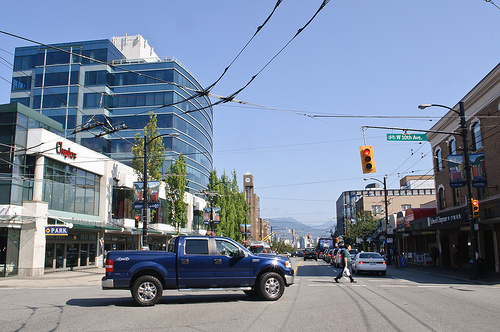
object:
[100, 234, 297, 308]
truck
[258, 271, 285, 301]
wheel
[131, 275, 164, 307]
wheel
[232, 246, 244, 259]
mirror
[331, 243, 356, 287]
man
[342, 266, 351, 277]
grocery bag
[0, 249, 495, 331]
street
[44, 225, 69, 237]
parking sign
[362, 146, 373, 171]
stoplight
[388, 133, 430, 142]
street sign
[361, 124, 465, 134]
pole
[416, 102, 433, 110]
street light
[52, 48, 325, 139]
electric cables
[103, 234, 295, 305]
back of truck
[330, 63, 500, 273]
buildings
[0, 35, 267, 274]
buildings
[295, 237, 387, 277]
vehicles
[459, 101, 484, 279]
pole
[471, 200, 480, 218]
street light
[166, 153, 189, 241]
tree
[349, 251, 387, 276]
car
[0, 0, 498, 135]
sky